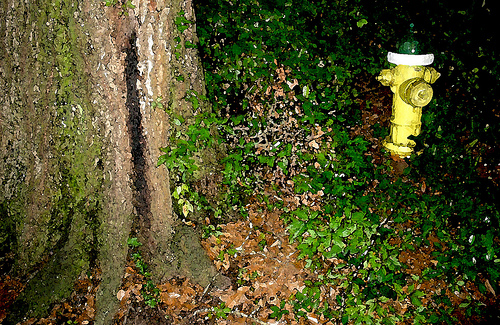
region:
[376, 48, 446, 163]
A yellow fire hydrant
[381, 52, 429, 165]
A dirty fire hydrant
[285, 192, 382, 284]
Green leaves by the floor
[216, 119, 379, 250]
A small bush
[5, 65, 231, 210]
The trunk of a tree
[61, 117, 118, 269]
Moss on a tree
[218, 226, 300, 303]
Diret and leaves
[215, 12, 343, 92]
A bush with green leaves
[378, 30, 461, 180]
A fire hydrant in the bushes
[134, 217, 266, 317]
The roots of the tree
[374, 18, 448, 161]
a yellow fire hydrant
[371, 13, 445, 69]
the green and white top of the fire hydrant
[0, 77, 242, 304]
the base of a tree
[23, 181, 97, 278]
moss growing on the tree trunk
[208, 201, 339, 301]
dead leaves on the ground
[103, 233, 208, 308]
vine growing at the base of the tree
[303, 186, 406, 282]
green leaves on the ground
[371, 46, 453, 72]
white stripe on the top of the fire hydrant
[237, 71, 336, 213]
dead tree branches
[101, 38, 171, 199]
mold growing on the trunk of the tree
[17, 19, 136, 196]
moss covered tree trunk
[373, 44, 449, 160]
yellow fire hydrant in leaves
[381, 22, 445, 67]
green and white top of hydrant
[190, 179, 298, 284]
dirt at base of tree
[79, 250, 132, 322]
root of tree trunk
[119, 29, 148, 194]
dark discoloration in tree trunk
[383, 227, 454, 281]
dark dirt patch in leaves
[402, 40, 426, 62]
reflection on top of hydrant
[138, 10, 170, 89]
light discoloration on tree bark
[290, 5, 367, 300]
Green foliage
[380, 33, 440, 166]
Yellow fire hydrant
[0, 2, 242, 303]
A moss-covered tree trunk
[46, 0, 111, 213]
A long strand of moss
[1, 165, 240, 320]
The base of the tree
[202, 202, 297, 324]
Brown foliage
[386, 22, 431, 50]
Green cap of the fire hydrant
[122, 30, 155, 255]
A large, natural figure formation in the tree's base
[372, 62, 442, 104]
Three fire hydrant hose spigots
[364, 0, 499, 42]
Dark and shadowy area in the background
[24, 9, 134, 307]
moss on the tree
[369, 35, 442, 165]
yellow and green fire hydrant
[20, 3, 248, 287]
brown tree bark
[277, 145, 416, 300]
green leafy plants surround the tree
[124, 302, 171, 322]
dirt in front of the tree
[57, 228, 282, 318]
the tops of tree roots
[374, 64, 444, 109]
valves on the fire hydrant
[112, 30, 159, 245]
damp tree bark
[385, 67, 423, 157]
chipped yellow paint on a fire hydrant